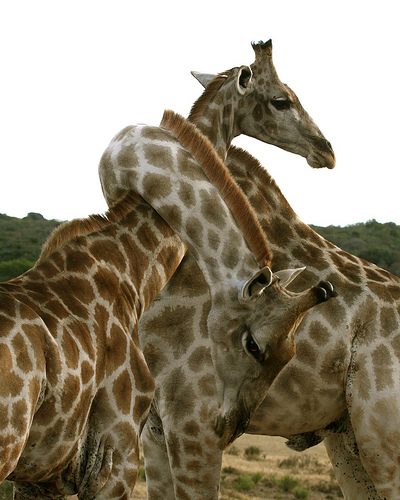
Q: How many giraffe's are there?
A: Two.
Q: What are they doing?
A: Hugging.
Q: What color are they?
A: Brown and white.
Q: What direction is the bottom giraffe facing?
A: Down.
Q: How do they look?
A: Happy.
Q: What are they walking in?
A: Sand.